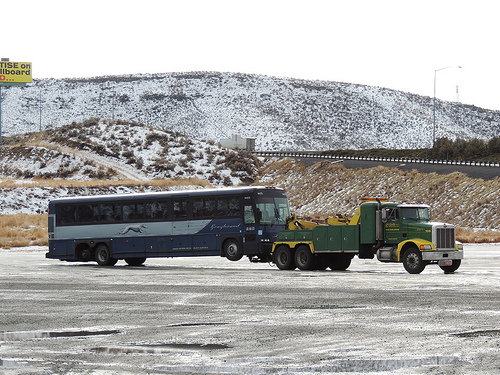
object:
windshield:
[243, 192, 290, 230]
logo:
[116, 224, 148, 235]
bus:
[43, 184, 294, 266]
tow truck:
[269, 197, 464, 275]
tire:
[402, 247, 426, 274]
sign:
[0, 61, 34, 85]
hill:
[0, 72, 499, 180]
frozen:
[0, 268, 498, 374]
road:
[258, 151, 500, 178]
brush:
[2, 118, 262, 184]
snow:
[14, 69, 269, 185]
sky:
[0, 0, 500, 112]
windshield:
[397, 202, 431, 220]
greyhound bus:
[37, 184, 464, 277]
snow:
[274, 299, 478, 358]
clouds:
[0, 0, 498, 109]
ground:
[0, 270, 497, 373]